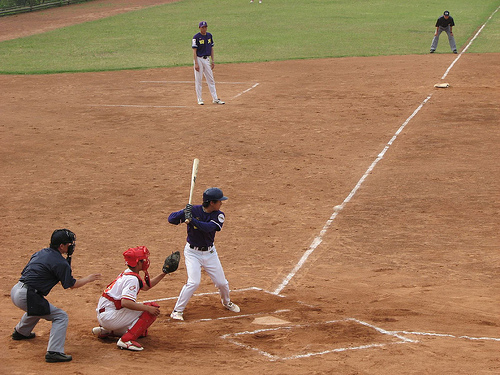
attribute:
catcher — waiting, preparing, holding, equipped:
[10, 223, 104, 371]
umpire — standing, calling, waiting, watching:
[424, 8, 465, 57]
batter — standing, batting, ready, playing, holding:
[156, 154, 264, 330]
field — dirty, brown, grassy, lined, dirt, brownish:
[3, 7, 499, 374]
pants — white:
[192, 55, 220, 100]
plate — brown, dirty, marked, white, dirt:
[239, 312, 302, 332]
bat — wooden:
[179, 153, 206, 227]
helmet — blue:
[201, 185, 231, 204]